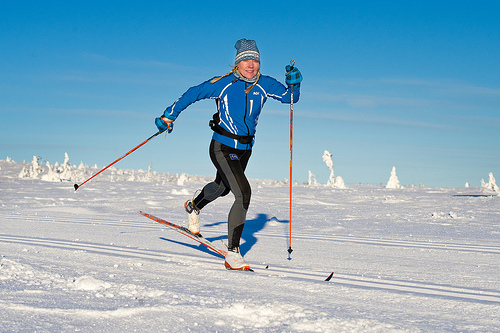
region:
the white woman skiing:
[72, 35, 334, 282]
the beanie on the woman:
[235, 37, 261, 62]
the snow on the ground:
[335, 184, 467, 231]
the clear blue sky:
[306, 7, 488, 71]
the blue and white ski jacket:
[152, 75, 302, 151]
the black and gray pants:
[193, 140, 265, 249]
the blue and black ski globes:
[285, 66, 302, 87]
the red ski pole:
[287, 57, 292, 260]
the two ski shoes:
[134, 209, 334, 287]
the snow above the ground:
[304, 150, 401, 191]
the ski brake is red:
[285, 57, 299, 267]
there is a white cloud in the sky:
[316, 90, 443, 142]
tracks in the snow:
[8, 223, 126, 267]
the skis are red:
[132, 196, 263, 284]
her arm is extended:
[147, 70, 215, 144]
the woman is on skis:
[193, 29, 278, 259]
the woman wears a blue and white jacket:
[167, 70, 284, 147]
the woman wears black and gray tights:
[197, 133, 256, 243]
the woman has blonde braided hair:
[202, 67, 236, 87]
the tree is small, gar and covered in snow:
[375, 158, 406, 196]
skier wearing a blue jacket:
[67, 33, 390, 260]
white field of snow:
[16, 138, 465, 300]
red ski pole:
[271, 57, 313, 266]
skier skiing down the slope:
[103, 13, 364, 235]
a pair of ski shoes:
[175, 192, 272, 280]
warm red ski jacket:
[153, 63, 317, 151]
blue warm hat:
[231, 33, 270, 65]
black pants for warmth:
[173, 125, 274, 262]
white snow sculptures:
[302, 142, 414, 198]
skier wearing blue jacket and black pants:
[91, 25, 376, 263]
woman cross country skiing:
[56, 16, 358, 276]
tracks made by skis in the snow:
[32, 221, 116, 272]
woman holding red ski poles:
[65, 108, 191, 212]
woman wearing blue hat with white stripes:
[225, 29, 284, 69]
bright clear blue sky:
[32, 13, 165, 87]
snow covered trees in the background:
[304, 131, 491, 197]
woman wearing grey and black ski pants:
[155, 140, 268, 271]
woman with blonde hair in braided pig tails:
[193, 29, 273, 103]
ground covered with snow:
[339, 193, 448, 255]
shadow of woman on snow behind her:
[208, 193, 303, 270]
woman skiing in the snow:
[60, 26, 370, 297]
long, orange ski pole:
[281, 80, 301, 265]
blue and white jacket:
[135, 68, 307, 155]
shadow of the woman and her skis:
[158, 196, 283, 271]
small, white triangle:
[380, 161, 403, 193]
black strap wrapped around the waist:
[205, 115, 260, 151]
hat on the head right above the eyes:
[224, 30, 268, 70]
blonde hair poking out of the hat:
[204, 63, 243, 85]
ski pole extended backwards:
[55, 96, 187, 197]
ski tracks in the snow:
[281, 267, 498, 308]